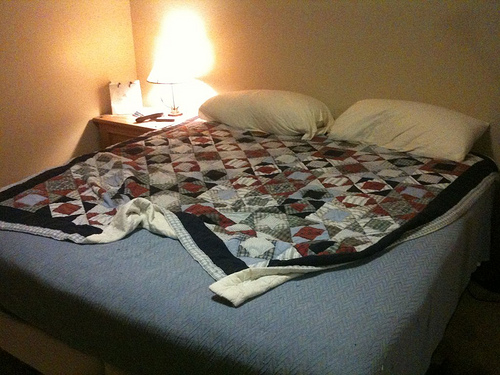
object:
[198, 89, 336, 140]
pillow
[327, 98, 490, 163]
pillow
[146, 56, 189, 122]
lamp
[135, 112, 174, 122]
remote control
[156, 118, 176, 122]
remote control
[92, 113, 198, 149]
bedside table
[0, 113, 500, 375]
bed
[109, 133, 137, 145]
drawer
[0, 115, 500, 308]
quilt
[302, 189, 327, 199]
square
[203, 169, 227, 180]
square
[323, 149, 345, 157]
square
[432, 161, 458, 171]
square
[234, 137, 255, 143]
square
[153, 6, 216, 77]
lamp shade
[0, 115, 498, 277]
lining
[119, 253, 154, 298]
bottom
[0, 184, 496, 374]
sheet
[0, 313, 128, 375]
box spring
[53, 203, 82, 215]
square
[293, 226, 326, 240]
square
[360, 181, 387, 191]
square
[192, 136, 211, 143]
square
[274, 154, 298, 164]
square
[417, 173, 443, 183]
square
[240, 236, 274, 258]
square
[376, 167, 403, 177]
square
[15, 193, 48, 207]
square